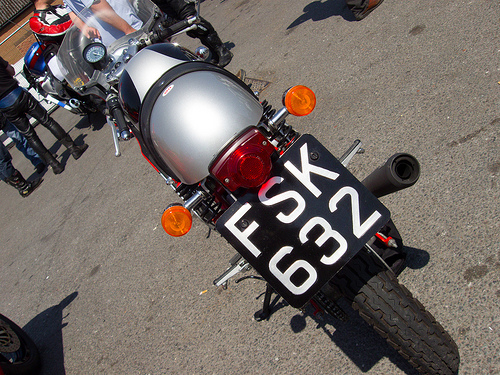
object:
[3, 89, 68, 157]
pants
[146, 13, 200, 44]
handle bar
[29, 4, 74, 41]
jacket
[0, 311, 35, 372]
tire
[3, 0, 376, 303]
tarmack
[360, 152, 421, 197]
exhaust pipe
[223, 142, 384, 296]
color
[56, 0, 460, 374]
bike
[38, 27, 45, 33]
leather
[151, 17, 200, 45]
handle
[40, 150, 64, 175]
black shoes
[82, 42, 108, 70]
speedometer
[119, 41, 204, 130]
tank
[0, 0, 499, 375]
picture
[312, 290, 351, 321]
chain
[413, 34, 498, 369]
lot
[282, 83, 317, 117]
light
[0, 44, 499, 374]
floor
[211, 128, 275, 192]
light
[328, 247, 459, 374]
back tire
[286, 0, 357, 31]
shadow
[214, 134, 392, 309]
license plate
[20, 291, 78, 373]
shadow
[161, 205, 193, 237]
light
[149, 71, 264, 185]
frame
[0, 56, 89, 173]
person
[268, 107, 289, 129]
spring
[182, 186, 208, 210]
spring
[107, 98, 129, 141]
handle